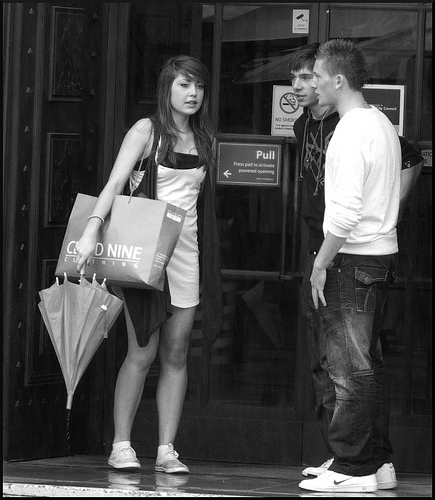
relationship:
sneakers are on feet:
[105, 437, 193, 480] [101, 431, 197, 478]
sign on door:
[215, 141, 282, 185] [201, 0, 317, 387]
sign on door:
[271, 82, 305, 139] [204, 3, 318, 457]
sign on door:
[216, 141, 287, 186] [123, 1, 302, 470]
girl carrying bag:
[70, 50, 214, 484] [55, 116, 188, 291]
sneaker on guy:
[297, 472, 376, 492] [299, 36, 401, 498]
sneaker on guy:
[376, 464, 398, 489] [299, 36, 401, 498]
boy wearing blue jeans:
[297, 38, 403, 493] [315, 252, 394, 476]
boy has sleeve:
[297, 38, 403, 493] [321, 145, 366, 231]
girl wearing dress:
[74, 52, 217, 474] [107, 121, 222, 310]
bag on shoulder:
[55, 116, 188, 291] [126, 115, 162, 147]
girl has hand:
[74, 52, 217, 474] [59, 227, 115, 278]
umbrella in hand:
[32, 212, 126, 448] [59, 227, 115, 278]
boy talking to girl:
[297, 38, 403, 493] [74, 52, 217, 474]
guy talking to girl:
[286, 41, 425, 478] [74, 52, 217, 474]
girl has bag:
[74, 52, 217, 474] [55, 116, 188, 291]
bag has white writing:
[55, 116, 188, 291] [59, 237, 144, 271]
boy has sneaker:
[297, 38, 403, 493] [295, 471, 380, 495]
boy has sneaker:
[297, 38, 403, 493] [379, 462, 397, 487]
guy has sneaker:
[286, 41, 425, 478] [302, 457, 336, 477]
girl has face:
[74, 52, 217, 474] [167, 77, 214, 125]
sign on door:
[215, 141, 282, 185] [4, 2, 227, 467]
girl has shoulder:
[70, 50, 214, 484] [124, 115, 158, 151]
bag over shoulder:
[55, 116, 188, 291] [124, 115, 158, 151]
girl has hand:
[70, 50, 214, 484] [70, 224, 104, 273]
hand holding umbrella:
[70, 224, 104, 273] [34, 255, 130, 421]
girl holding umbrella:
[70, 50, 214, 484] [34, 255, 130, 421]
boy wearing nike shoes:
[307, 34, 403, 489] [296, 448, 391, 493]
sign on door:
[216, 141, 281, 186] [213, 2, 301, 296]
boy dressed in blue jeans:
[297, 38, 403, 493] [315, 251, 390, 475]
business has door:
[0, 27, 421, 470] [193, 0, 324, 466]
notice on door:
[291, 8, 309, 35] [193, 0, 324, 466]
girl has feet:
[74, 52, 217, 474] [96, 440, 198, 479]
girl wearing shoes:
[74, 52, 217, 474] [101, 440, 195, 474]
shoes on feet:
[101, 440, 195, 474] [96, 440, 198, 479]